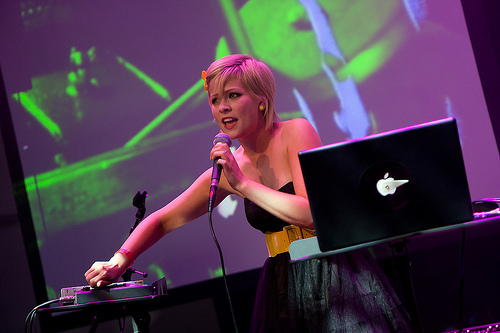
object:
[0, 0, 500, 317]
screen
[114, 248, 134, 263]
band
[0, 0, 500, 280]
backgroud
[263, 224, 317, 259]
belt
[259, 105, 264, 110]
earring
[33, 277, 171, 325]
board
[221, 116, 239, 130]
mouth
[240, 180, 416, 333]
dress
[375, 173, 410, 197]
logo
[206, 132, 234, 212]
mic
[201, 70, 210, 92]
clip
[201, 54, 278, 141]
head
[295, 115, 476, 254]
computer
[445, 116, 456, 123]
corner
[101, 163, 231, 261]
arm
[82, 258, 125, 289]
hand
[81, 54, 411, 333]
girl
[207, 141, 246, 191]
hand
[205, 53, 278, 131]
hair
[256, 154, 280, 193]
shadow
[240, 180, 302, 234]
chest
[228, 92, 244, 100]
eye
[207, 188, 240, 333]
cord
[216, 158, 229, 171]
finger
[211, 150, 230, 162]
fingers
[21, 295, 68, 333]
cable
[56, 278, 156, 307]
machine